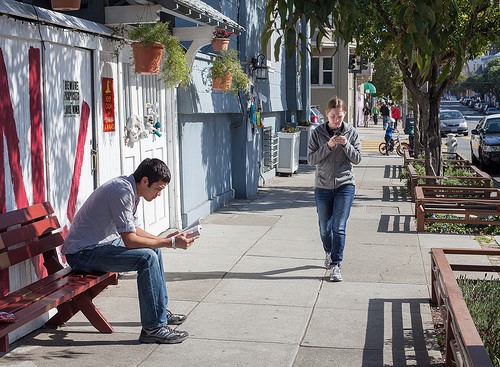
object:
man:
[60, 157, 202, 345]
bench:
[0, 198, 123, 358]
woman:
[306, 97, 363, 283]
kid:
[383, 118, 397, 156]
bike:
[378, 129, 410, 157]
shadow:
[118, 264, 330, 281]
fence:
[405, 162, 494, 204]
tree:
[256, 3, 498, 187]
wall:
[0, 14, 190, 334]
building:
[0, 0, 312, 351]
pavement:
[0, 128, 500, 367]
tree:
[477, 54, 498, 108]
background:
[294, 0, 500, 126]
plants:
[127, 20, 194, 92]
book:
[172, 216, 205, 237]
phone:
[334, 132, 341, 136]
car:
[469, 114, 500, 172]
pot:
[130, 42, 165, 76]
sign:
[101, 76, 115, 133]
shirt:
[384, 125, 396, 139]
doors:
[125, 62, 176, 232]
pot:
[276, 130, 302, 177]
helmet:
[387, 118, 397, 124]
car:
[438, 109, 469, 137]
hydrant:
[445, 133, 458, 160]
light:
[255, 65, 270, 80]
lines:
[361, 149, 404, 151]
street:
[97, 129, 500, 311]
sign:
[62, 77, 80, 118]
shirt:
[380, 105, 391, 117]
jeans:
[312, 183, 356, 266]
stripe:
[24, 44, 50, 203]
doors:
[0, 40, 94, 308]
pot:
[212, 66, 234, 91]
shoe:
[137, 326, 190, 345]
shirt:
[306, 120, 363, 190]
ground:
[0, 121, 500, 365]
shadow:
[376, 214, 418, 234]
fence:
[413, 185, 500, 234]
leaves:
[220, 76, 222, 78]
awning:
[0, 0, 123, 40]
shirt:
[371, 107, 381, 116]